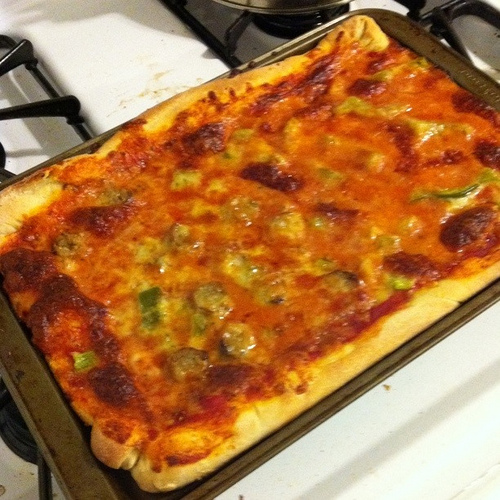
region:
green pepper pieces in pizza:
[118, 259, 259, 371]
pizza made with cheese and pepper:
[72, 149, 417, 388]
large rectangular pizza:
[46, 111, 439, 405]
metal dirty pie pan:
[7, 344, 143, 498]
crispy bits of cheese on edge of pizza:
[102, 120, 148, 170]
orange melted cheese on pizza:
[201, 131, 403, 274]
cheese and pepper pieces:
[117, 249, 259, 369]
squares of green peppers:
[129, 285, 179, 330]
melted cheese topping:
[192, 87, 452, 302]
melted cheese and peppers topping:
[139, 239, 282, 355]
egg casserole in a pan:
[15, 22, 427, 479]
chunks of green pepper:
[131, 267, 269, 379]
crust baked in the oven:
[112, 414, 242, 476]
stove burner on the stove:
[2, 34, 94, 145]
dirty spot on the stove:
[92, 31, 177, 112]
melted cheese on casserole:
[282, 88, 434, 225]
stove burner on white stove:
[211, 8, 291, 68]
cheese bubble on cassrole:
[168, 110, 236, 168]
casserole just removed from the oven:
[164, 82, 378, 306]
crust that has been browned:
[218, 327, 386, 404]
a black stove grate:
[0, 28, 100, 191]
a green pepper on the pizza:
[131, 285, 166, 315]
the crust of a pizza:
[0, 5, 390, 235]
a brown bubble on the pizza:
[181, 111, 227, 158]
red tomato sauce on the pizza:
[182, 390, 237, 425]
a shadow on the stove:
[4, 0, 229, 62]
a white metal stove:
[0, 0, 497, 497]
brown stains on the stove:
[120, 57, 192, 110]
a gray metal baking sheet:
[0, 5, 499, 498]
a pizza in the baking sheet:
[0, 10, 499, 497]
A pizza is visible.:
[16, 83, 310, 445]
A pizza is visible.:
[53, 25, 265, 321]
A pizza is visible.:
[102, 218, 317, 497]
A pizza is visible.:
[138, 141, 342, 431]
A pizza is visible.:
[171, 289, 278, 490]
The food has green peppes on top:
[86, 229, 306, 338]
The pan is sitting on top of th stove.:
[34, 90, 448, 380]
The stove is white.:
[338, 396, 463, 491]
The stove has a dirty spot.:
[93, 46, 198, 105]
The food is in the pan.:
[63, 130, 412, 412]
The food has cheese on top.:
[52, 150, 420, 418]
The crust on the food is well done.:
[96, 409, 250, 487]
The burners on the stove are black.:
[5, 35, 95, 141]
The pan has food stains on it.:
[15, 331, 74, 457]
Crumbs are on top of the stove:
[379, 370, 411, 433]